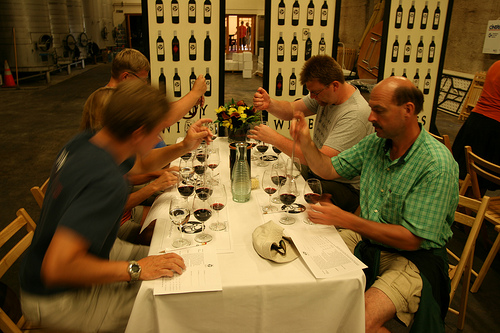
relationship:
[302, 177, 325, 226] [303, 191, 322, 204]
glass has red wine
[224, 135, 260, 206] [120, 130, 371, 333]
vase on table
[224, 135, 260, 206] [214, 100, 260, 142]
vase has flowers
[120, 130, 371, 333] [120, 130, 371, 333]
table on table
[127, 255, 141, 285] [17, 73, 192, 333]
watch on man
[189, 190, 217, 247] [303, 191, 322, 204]
glass has red wine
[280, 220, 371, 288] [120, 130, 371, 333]
paper on table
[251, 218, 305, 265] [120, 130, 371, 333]
ball cap on table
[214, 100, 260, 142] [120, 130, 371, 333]
flowers on top of table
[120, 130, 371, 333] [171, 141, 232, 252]
table full of drinks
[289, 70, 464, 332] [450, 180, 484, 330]
man sitting on chair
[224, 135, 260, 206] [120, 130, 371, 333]
vase in middle of table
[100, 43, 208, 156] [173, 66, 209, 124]
man raises h hand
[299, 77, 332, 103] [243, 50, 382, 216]
glasses on man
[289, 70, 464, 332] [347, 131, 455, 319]
man wearing clothes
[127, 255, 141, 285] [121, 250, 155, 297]
watch on wrist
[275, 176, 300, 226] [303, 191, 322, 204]
glass has red wine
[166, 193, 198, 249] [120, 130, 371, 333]
glass on table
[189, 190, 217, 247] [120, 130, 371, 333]
glass on table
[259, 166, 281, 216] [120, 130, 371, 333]
glass on table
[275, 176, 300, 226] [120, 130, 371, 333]
glass on table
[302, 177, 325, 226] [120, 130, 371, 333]
glass on table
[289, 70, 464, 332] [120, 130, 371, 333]
person seated at table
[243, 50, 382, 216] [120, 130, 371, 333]
person seated at table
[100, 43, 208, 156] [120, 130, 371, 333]
person seated at table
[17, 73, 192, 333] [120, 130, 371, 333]
person seated at table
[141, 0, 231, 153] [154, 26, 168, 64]
divider has picture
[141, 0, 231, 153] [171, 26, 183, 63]
divider has picture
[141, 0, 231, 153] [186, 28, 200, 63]
divider has picture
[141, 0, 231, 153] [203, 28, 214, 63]
divider has picture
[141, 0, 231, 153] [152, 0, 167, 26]
divider has picture